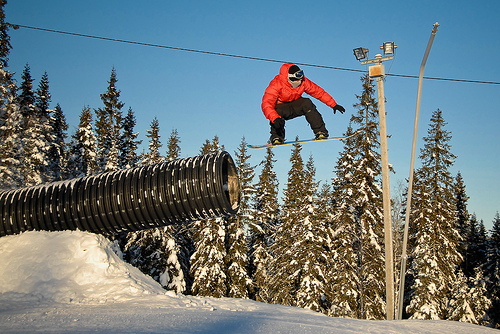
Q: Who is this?
A: A man.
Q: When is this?
A: Daytime.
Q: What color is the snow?
A: White.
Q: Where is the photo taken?
A: At a ski slope.